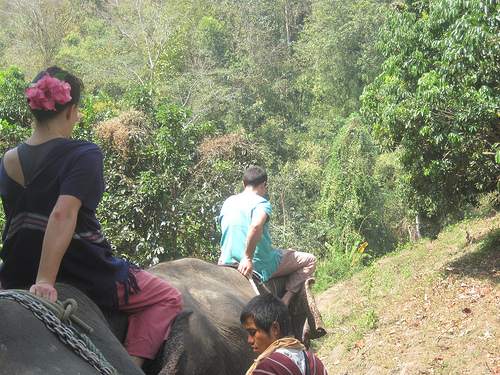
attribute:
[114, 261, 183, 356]
pants — pink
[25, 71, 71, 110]
flower — pink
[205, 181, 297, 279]
shirt — baby blue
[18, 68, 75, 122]
flower — pink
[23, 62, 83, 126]
hair — woman's